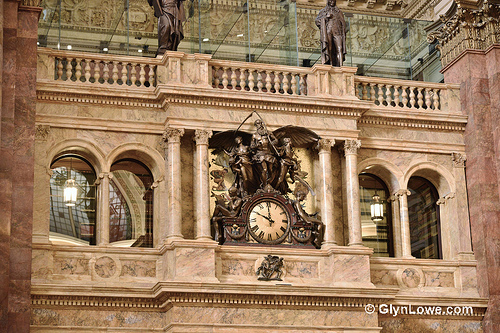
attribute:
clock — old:
[194, 117, 334, 258]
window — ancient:
[357, 162, 400, 256]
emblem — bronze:
[255, 245, 287, 284]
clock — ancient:
[248, 201, 288, 243]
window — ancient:
[51, 157, 158, 243]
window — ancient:
[56, 162, 114, 324]